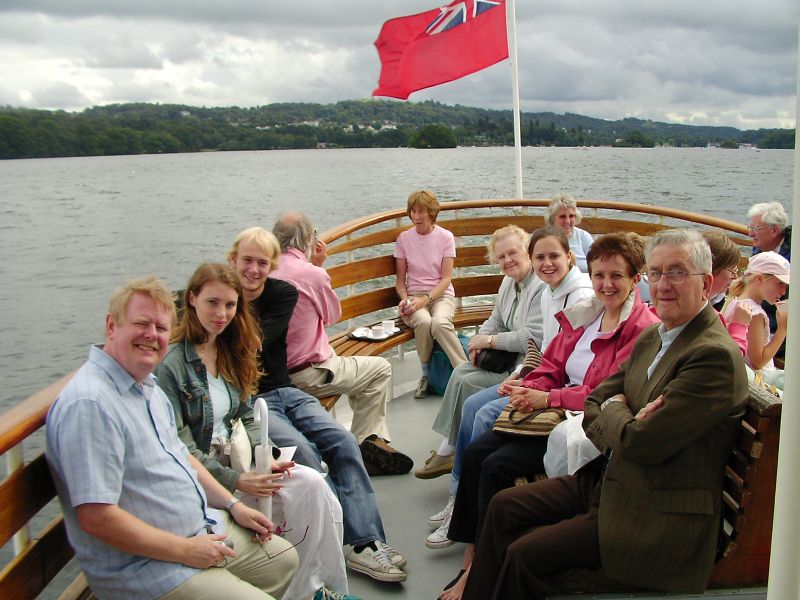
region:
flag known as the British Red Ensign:
[368, 0, 517, 94]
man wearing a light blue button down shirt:
[46, 337, 236, 598]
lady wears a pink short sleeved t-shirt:
[385, 214, 465, 305]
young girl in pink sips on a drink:
[726, 239, 799, 379]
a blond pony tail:
[722, 275, 746, 303]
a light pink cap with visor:
[742, 248, 791, 293]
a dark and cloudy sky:
[0, 0, 798, 113]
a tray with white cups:
[345, 307, 404, 353]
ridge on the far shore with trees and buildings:
[3, 102, 782, 154]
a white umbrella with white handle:
[242, 399, 282, 519]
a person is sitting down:
[80, 282, 284, 594]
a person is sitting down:
[156, 250, 350, 590]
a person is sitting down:
[216, 225, 411, 580]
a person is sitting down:
[265, 205, 421, 480]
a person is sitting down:
[387, 165, 464, 384]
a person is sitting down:
[472, 224, 723, 586]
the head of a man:
[109, 285, 209, 387]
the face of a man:
[116, 280, 200, 373]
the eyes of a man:
[107, 310, 200, 360]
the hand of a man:
[176, 513, 251, 583]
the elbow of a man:
[52, 481, 150, 570]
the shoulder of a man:
[25, 367, 146, 490]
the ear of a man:
[98, 310, 146, 355]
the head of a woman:
[182, 278, 250, 342]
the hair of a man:
[86, 271, 170, 341]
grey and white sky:
[25, 6, 293, 89]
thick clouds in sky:
[35, 21, 255, 77]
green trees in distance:
[98, 89, 418, 151]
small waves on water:
[61, 185, 207, 247]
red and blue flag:
[378, 4, 486, 109]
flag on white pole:
[507, 17, 533, 196]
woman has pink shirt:
[385, 225, 450, 316]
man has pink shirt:
[275, 248, 333, 360]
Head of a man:
[97, 278, 175, 375]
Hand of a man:
[182, 529, 240, 572]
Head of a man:
[643, 227, 716, 327]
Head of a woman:
[181, 262, 246, 339]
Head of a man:
[229, 226, 279, 290]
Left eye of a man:
[240, 254, 253, 272]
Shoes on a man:
[354, 532, 411, 589]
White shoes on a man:
[344, 536, 411, 590]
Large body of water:
[49, 161, 189, 249]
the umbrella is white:
[245, 401, 285, 554]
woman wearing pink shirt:
[386, 193, 475, 375]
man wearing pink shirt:
[267, 215, 408, 469]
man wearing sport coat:
[475, 241, 747, 587]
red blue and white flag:
[374, 7, 508, 117]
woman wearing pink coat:
[505, 247, 657, 468]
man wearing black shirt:
[226, 234, 389, 576]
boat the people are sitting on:
[6, 180, 742, 597]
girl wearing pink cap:
[726, 249, 793, 383]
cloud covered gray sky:
[8, 11, 798, 145]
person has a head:
[184, 265, 238, 331]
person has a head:
[100, 284, 173, 375]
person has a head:
[274, 215, 320, 256]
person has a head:
[486, 222, 529, 276]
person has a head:
[524, 228, 568, 279]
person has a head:
[548, 195, 578, 232]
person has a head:
[586, 238, 640, 297]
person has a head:
[644, 232, 718, 317]